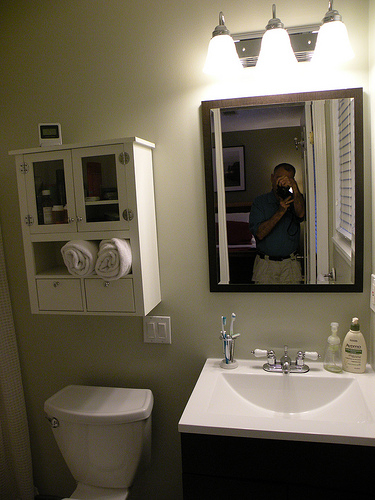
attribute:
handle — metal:
[42, 415, 59, 428]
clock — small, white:
[36, 123, 64, 146]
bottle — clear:
[326, 322, 342, 377]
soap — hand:
[326, 363, 344, 373]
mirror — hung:
[195, 83, 370, 298]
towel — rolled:
[57, 227, 135, 274]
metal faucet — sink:
[250, 342, 320, 375]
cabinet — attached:
[20, 128, 163, 249]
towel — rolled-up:
[96, 238, 132, 280]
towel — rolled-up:
[60, 238, 95, 275]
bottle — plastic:
[317, 319, 341, 374]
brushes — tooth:
[214, 303, 245, 358]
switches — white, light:
[104, 296, 197, 360]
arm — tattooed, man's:
[260, 200, 293, 229]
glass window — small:
[28, 157, 70, 223]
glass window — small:
[23, 151, 128, 229]